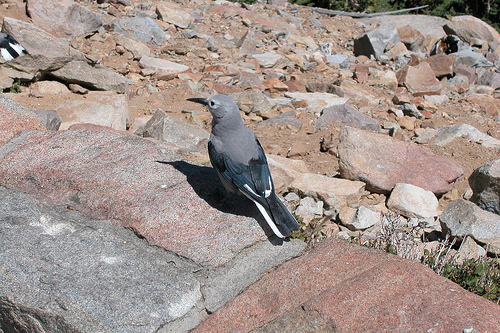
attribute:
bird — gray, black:
[188, 92, 311, 258]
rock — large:
[304, 117, 471, 220]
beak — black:
[181, 89, 207, 107]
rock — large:
[140, 107, 212, 151]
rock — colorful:
[397, 62, 442, 94]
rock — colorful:
[353, 29, 388, 57]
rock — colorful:
[251, 50, 283, 66]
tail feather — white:
[258, 200, 288, 239]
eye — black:
[211, 101, 215, 106]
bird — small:
[187, 92, 299, 237]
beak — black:
[186, 95, 208, 105]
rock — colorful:
[137, 54, 192, 79]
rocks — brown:
[124, 13, 498, 285]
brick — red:
[342, 140, 486, 297]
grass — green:
[417, 198, 466, 258]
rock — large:
[360, 12, 401, 59]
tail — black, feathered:
[257, 191, 300, 239]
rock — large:
[2, 15, 93, 73]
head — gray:
[206, 92, 238, 123]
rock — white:
[391, 180, 443, 220]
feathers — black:
[252, 199, 305, 246]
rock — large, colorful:
[335, 123, 472, 193]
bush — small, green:
[421, 237, 499, 301]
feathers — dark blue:
[223, 142, 283, 195]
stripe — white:
[242, 182, 264, 199]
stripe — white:
[262, 173, 272, 196]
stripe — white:
[237, 188, 287, 240]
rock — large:
[384, 181, 442, 220]